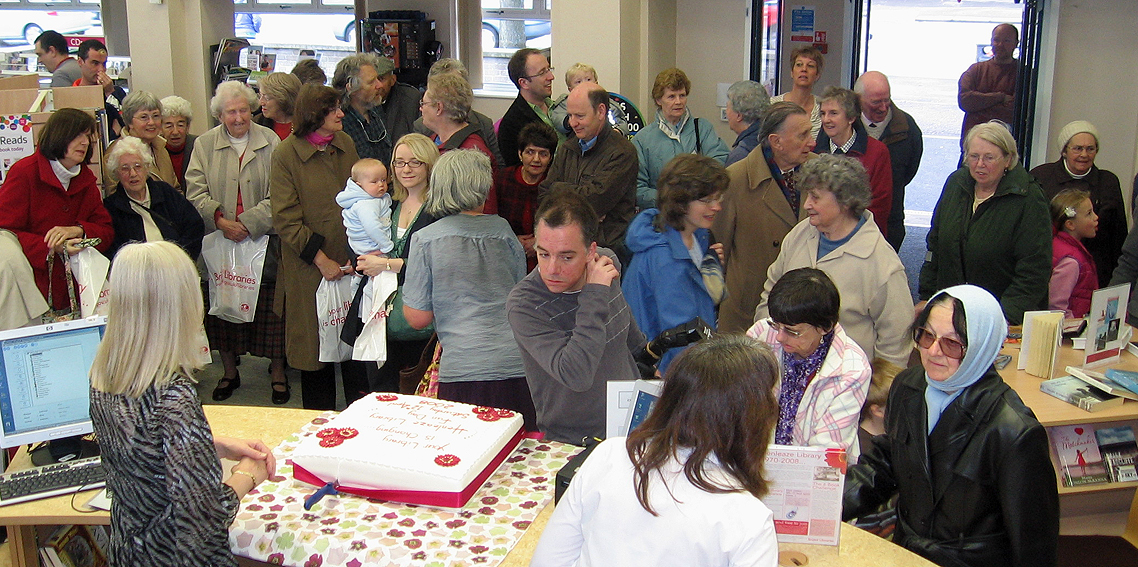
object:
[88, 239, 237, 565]
woman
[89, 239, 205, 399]
hair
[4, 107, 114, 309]
woman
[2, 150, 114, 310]
coat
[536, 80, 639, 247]
man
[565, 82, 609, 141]
head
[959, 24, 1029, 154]
man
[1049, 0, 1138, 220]
wall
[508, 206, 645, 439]
man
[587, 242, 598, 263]
ear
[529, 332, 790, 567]
woman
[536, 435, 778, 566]
shirt